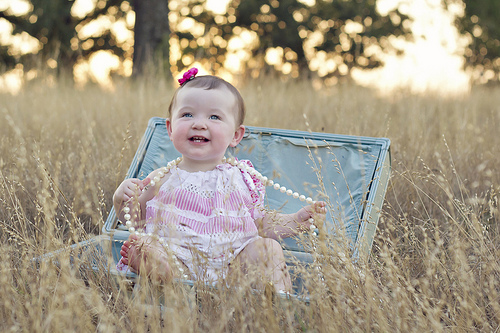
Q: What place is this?
A: It is a field.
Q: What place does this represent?
A: It represents the field.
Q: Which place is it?
A: It is a field.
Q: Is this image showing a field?
A: Yes, it is showing a field.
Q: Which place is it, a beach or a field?
A: It is a field.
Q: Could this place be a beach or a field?
A: It is a field.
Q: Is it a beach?
A: No, it is a field.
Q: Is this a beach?
A: No, it is a field.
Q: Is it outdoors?
A: Yes, it is outdoors.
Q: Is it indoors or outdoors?
A: It is outdoors.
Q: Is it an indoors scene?
A: No, it is outdoors.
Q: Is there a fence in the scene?
A: No, there are no fences.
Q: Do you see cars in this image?
A: No, there are no cars.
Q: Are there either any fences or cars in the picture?
A: No, there are no cars or fences.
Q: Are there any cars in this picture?
A: No, there are no cars.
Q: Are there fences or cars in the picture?
A: No, there are no cars or fences.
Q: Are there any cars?
A: No, there are no cars.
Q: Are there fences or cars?
A: No, there are no cars or fences.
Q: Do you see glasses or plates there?
A: No, there are no glasses or plates.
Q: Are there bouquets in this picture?
A: No, there are no bouquets.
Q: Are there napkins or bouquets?
A: No, there are no bouquets or napkins.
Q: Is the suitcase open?
A: Yes, the suitcase is open.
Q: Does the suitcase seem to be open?
A: Yes, the suitcase is open.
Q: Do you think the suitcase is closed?
A: No, the suitcase is open.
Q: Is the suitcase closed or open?
A: The suitcase is open.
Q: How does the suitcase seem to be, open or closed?
A: The suitcase is open.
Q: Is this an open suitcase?
A: Yes, this is an open suitcase.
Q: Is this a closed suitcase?
A: No, this is an open suitcase.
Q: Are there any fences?
A: No, there are no fences.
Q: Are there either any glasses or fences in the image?
A: No, there are no fences or glasses.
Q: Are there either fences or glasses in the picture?
A: No, there are no fences or glasses.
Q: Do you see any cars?
A: No, there are no cars.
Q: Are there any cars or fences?
A: No, there are no cars or fences.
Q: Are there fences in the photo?
A: No, there are no fences.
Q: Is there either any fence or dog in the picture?
A: No, there are no fences or dogs.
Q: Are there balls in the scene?
A: No, there are no balls.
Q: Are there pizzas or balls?
A: No, there are no balls or pizzas.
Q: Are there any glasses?
A: No, there are no glasses.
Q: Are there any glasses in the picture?
A: No, there are no glasses.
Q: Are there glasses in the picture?
A: No, there are no glasses.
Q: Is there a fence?
A: No, there are no fences.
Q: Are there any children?
A: Yes, there is a child.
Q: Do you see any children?
A: Yes, there is a child.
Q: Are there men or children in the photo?
A: Yes, there is a child.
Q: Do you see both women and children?
A: No, there is a child but no women.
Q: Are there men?
A: No, there are no men.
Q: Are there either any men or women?
A: No, there are no men or women.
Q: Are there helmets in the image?
A: No, there are no helmets.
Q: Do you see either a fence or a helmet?
A: No, there are no helmets or fences.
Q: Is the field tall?
A: Yes, the field is tall.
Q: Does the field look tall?
A: Yes, the field is tall.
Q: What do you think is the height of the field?
A: The field is tall.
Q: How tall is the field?
A: The field is tall.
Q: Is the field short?
A: No, the field is tall.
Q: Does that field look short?
A: No, the field is tall.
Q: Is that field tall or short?
A: The field is tall.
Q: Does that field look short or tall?
A: The field is tall.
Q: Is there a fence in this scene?
A: No, there are no fences.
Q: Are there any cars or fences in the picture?
A: No, there are no fences or cars.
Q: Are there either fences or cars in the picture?
A: No, there are no fences or cars.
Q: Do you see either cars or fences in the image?
A: No, there are no fences or cars.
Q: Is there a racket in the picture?
A: No, there are no rackets.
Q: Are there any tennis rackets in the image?
A: No, there are no tennis rackets.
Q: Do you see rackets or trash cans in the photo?
A: No, there are no rackets or trash cans.